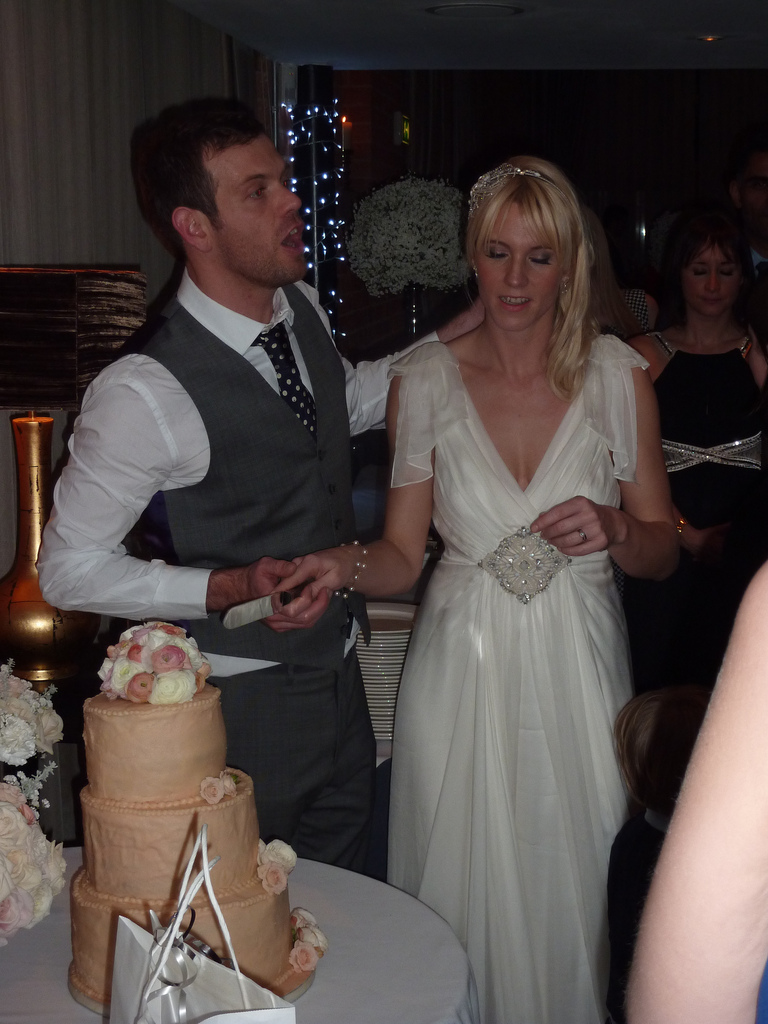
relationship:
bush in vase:
[344, 179, 476, 296] [394, 283, 428, 343]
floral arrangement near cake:
[0, 657, 69, 943] [65, 622, 333, 1021]